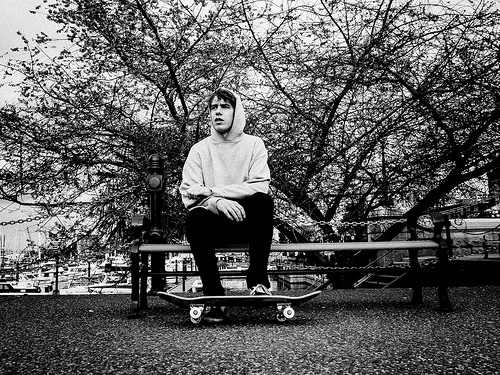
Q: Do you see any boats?
A: Yes, there is a boat.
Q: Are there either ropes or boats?
A: Yes, there is a boat.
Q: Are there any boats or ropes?
A: Yes, there is a boat.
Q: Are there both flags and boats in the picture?
A: No, there is a boat but no flags.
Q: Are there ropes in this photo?
A: No, there are no ropes.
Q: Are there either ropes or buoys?
A: No, there are no ropes or buoys.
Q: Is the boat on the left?
A: Yes, the boat is on the left of the image.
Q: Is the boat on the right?
A: No, the boat is on the left of the image.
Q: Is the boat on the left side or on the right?
A: The boat is on the left of the image.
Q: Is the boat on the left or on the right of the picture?
A: The boat is on the left of the image.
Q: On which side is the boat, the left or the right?
A: The boat is on the left of the image.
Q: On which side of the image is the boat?
A: The boat is on the left of the image.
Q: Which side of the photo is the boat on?
A: The boat is on the left of the image.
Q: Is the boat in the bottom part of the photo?
A: Yes, the boat is in the bottom of the image.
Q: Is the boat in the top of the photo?
A: No, the boat is in the bottom of the image.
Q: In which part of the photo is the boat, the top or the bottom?
A: The boat is in the bottom of the image.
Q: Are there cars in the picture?
A: No, there are no cars.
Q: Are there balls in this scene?
A: No, there are no balls.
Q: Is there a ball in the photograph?
A: No, there are no balls.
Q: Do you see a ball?
A: No, there are no balls.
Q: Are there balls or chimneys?
A: No, there are no balls or chimneys.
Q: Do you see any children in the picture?
A: No, there are no children.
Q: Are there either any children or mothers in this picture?
A: No, there are no children or mothers.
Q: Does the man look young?
A: Yes, the man is young.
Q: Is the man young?
A: Yes, the man is young.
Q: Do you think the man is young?
A: Yes, the man is young.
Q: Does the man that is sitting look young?
A: Yes, the man is young.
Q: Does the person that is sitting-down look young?
A: Yes, the man is young.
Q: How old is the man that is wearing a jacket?
A: The man is young.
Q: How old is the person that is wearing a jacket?
A: The man is young.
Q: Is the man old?
A: No, the man is young.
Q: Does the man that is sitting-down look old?
A: No, the man is young.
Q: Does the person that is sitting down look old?
A: No, the man is young.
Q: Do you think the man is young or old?
A: The man is young.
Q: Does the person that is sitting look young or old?
A: The man is young.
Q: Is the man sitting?
A: Yes, the man is sitting.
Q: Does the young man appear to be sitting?
A: Yes, the man is sitting.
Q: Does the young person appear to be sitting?
A: Yes, the man is sitting.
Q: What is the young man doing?
A: The man is sitting.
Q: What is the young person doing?
A: The man is sitting.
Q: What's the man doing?
A: The man is sitting.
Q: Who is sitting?
A: The man is sitting.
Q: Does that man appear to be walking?
A: No, the man is sitting.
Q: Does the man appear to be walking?
A: No, the man is sitting.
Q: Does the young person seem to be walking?
A: No, the man is sitting.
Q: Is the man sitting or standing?
A: The man is sitting.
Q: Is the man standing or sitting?
A: The man is sitting.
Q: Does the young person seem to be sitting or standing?
A: The man is sitting.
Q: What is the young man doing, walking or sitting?
A: The man is sitting.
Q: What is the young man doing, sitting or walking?
A: The man is sitting.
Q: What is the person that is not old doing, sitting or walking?
A: The man is sitting.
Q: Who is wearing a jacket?
A: The man is wearing a jacket.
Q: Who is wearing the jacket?
A: The man is wearing a jacket.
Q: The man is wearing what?
A: The man is wearing a jacket.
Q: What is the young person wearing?
A: The man is wearing a jacket.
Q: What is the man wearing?
A: The man is wearing a jacket.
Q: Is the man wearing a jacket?
A: Yes, the man is wearing a jacket.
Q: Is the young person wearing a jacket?
A: Yes, the man is wearing a jacket.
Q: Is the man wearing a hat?
A: No, the man is wearing a jacket.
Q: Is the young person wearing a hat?
A: No, the man is wearing a jacket.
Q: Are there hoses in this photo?
A: No, there are no hoses.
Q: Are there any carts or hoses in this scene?
A: No, there are no hoses or carts.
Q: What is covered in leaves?
A: The ground is covered in leaves.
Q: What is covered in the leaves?
A: The ground is covered in leaves.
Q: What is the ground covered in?
A: The ground is covered in leaves.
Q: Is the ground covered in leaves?
A: Yes, the ground is covered in leaves.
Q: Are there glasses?
A: No, there are no glasses.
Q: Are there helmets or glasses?
A: No, there are no glasses or helmets.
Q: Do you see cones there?
A: No, there are no cones.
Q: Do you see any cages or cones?
A: No, there are no cones or cages.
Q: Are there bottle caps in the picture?
A: No, there are no bottle caps.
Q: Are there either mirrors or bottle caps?
A: No, there are no bottle caps or mirrors.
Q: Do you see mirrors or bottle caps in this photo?
A: No, there are no bottle caps or mirrors.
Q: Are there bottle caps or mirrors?
A: No, there are no bottle caps or mirrors.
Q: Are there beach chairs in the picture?
A: No, there are no beach chairs.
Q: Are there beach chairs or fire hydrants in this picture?
A: No, there are no beach chairs or fire hydrants.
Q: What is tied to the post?
A: The chain is tied to the post.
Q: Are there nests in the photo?
A: No, there are no nests.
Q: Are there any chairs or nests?
A: No, there are no nests or chairs.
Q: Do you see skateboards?
A: Yes, there is a skateboard.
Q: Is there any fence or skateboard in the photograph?
A: Yes, there is a skateboard.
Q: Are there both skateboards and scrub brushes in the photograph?
A: No, there is a skateboard but no scrub brushes.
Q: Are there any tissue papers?
A: No, there are no tissue papers.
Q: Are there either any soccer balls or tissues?
A: No, there are no tissues or soccer balls.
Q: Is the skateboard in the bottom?
A: Yes, the skateboard is in the bottom of the image.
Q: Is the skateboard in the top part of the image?
A: No, the skateboard is in the bottom of the image.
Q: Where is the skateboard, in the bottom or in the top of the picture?
A: The skateboard is in the bottom of the image.